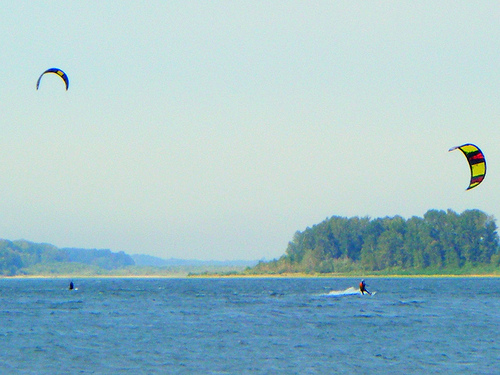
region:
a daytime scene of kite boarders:
[1, 1, 498, 373]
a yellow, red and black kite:
[448, 141, 484, 188]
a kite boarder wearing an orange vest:
[356, 276, 371, 291]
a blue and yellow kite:
[35, 65, 66, 87]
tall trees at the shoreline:
[255, 206, 495, 271]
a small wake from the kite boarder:
[321, 285, 356, 295]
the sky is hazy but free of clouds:
[0, 0, 496, 207]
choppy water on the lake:
[1, 298, 499, 373]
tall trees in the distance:
[1, 238, 287, 274]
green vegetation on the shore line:
[187, 266, 499, 278]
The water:
[238, 326, 312, 369]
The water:
[302, 315, 360, 371]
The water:
[264, 319, 342, 369]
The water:
[333, 338, 378, 365]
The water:
[287, 268, 369, 347]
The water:
[245, 246, 360, 343]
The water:
[220, 285, 375, 367]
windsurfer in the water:
[23, 60, 117, 311]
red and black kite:
[432, 128, 492, 213]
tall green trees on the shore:
[285, 208, 496, 279]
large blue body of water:
[7, 276, 498, 371]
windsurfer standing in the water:
[344, 267, 378, 309]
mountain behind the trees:
[119, 246, 278, 282]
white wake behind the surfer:
[327, 274, 364, 305]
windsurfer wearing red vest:
[352, 271, 378, 301]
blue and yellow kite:
[21, 63, 106, 108]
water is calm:
[28, 276, 459, 346]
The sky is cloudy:
[128, 68, 285, 192]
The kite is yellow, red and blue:
[428, 131, 490, 212]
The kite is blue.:
[15, 49, 106, 110]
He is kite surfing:
[343, 267, 395, 314]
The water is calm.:
[172, 304, 337, 374]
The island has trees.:
[260, 201, 496, 290]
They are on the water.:
[35, 263, 418, 338]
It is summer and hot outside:
[16, 13, 441, 371]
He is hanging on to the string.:
[340, 122, 496, 332]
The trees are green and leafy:
[256, 203, 496, 265]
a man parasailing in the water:
[342, 132, 490, 303]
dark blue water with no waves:
[91, 268, 248, 343]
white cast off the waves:
[323, 282, 360, 303]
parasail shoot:
[9, 58, 101, 98]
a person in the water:
[64, 273, 84, 297]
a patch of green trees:
[270, 195, 498, 285]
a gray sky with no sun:
[133, 98, 330, 211]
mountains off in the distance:
[17, 230, 282, 283]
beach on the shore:
[164, 262, 346, 288]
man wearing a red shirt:
[354, 272, 375, 292]